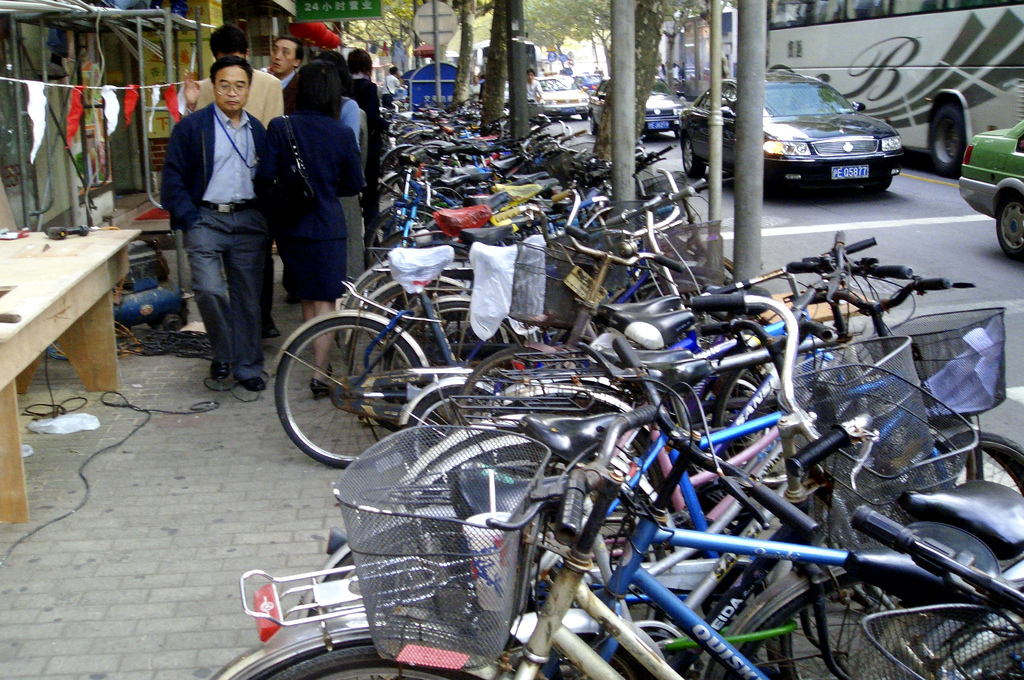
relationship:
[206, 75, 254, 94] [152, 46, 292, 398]
eyes of a man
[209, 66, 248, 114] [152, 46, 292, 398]
face of a man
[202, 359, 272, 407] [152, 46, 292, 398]
shoes of a man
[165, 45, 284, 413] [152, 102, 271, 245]
man wearing jacket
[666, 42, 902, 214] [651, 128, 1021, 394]
car on road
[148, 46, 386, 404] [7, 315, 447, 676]
people standing on sidewalk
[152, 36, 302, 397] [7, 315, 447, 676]
people standing on sidewalk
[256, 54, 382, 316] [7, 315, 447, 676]
people standing on sidewalk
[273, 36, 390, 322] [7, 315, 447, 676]
people standing on sidewalk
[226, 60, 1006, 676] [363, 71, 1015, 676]
line of bicycles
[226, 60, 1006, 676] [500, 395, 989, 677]
line of bicycle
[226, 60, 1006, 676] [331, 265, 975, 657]
line of bicycle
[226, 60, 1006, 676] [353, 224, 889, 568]
line of bicycle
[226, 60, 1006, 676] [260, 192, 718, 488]
line of bicycle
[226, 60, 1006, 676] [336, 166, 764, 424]
line of bicycle